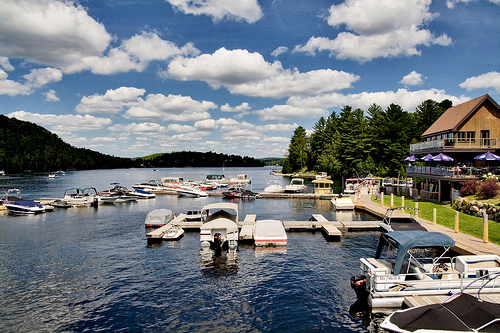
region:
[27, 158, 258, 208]
boats on the water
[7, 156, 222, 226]
boats on the water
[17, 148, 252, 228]
boats on the water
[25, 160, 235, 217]
boats on the water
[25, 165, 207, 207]
boats on the water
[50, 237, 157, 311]
the water is blue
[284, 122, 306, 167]
A tall green leaft tree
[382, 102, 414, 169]
A tall green leaft tree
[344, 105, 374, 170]
A tall green leaft tree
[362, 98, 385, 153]
A tall green leaft tree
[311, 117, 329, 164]
A tall green leaft tree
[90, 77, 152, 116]
A white cloud blue sky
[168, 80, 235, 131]
A white cloud blue sky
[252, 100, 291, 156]
A white cloud blue sky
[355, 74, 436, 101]
A white cloud blue sky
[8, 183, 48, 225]
this is a ship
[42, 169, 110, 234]
this is a ship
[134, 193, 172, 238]
this is a ship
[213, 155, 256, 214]
this is a ship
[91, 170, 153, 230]
this is a ship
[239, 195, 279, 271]
this is a ship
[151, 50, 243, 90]
this is a cloud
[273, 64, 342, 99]
this is a cloud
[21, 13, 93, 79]
this is a cloud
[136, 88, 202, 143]
this is a cloud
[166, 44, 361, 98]
white clouds in the sky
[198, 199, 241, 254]
a white boat at a dock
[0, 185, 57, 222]
a blue boat parked at a dock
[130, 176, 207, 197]
a white orange boat on the water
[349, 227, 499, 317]
a white blue boat on the water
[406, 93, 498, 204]
a brown house next to the water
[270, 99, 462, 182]
green trees behind the house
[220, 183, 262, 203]
a red and black boat on the water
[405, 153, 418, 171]
a purple umbrella next to a house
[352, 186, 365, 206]
people walking on a boardwalk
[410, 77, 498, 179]
a brown wooden house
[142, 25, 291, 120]
the white puffy clouds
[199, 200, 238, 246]
white boat in water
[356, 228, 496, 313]
white boat in water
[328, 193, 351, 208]
white boat in water